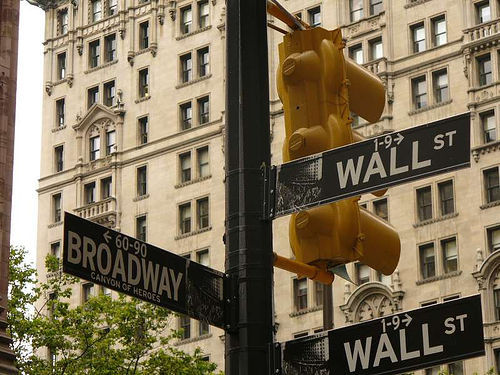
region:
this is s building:
[51, 43, 213, 172]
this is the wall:
[152, 155, 170, 185]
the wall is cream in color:
[152, 172, 176, 199]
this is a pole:
[215, 115, 272, 301]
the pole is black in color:
[225, 127, 272, 205]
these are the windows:
[180, 97, 210, 122]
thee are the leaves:
[50, 303, 140, 363]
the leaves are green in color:
[70, 308, 145, 364]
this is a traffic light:
[276, 38, 359, 125]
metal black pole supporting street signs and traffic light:
[221, 0, 277, 370]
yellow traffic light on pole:
[270, 0, 400, 282]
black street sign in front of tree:
[55, 207, 225, 317]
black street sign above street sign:
[272, 106, 467, 208]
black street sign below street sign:
[280, 291, 485, 367]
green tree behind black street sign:
[0, 240, 210, 370]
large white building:
[30, 0, 495, 370]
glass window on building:
[130, 160, 150, 195]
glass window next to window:
[175, 146, 190, 178]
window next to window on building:
[195, 142, 206, 175]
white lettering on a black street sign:
[64, 230, 184, 303]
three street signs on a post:
[61, 128, 481, 365]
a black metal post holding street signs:
[213, 42, 283, 369]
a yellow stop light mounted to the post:
[259, 5, 394, 290]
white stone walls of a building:
[153, 165, 178, 230]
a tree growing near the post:
[23, 243, 191, 374]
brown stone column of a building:
[0, 10, 26, 368]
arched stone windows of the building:
[463, 254, 498, 373]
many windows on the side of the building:
[145, 37, 232, 269]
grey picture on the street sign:
[276, 153, 321, 223]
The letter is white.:
[62, 227, 83, 266]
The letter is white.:
[79, 231, 99, 271]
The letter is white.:
[94, 238, 114, 277]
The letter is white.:
[110, 243, 127, 283]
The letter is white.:
[123, 248, 143, 286]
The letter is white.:
[140, 252, 160, 297]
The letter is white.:
[156, 259, 174, 299]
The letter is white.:
[168, 263, 187, 302]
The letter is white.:
[330, 153, 365, 190]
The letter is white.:
[362, 147, 389, 187]